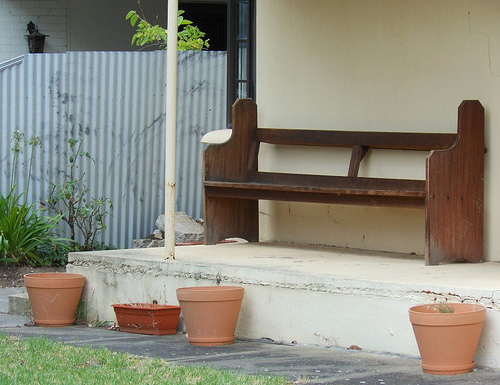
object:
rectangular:
[110, 297, 182, 334]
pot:
[108, 299, 179, 336]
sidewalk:
[97, 336, 358, 377]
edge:
[66, 253, 151, 281]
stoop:
[72, 256, 131, 329]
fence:
[33, 56, 156, 153]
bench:
[422, 149, 448, 264]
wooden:
[427, 151, 468, 268]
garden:
[50, 164, 105, 230]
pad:
[254, 235, 394, 327]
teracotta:
[95, 293, 189, 363]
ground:
[143, 338, 269, 379]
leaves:
[36, 138, 99, 233]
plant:
[49, 155, 109, 265]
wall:
[254, 318, 309, 383]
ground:
[18, 241, 159, 329]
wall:
[17, 52, 210, 213]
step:
[255, 258, 347, 315]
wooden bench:
[199, 98, 487, 263]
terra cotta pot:
[26, 271, 84, 329]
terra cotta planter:
[406, 300, 484, 374]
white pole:
[158, 3, 181, 258]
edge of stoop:
[6, 294, 33, 317]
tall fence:
[2, 40, 225, 253]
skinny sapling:
[5, 125, 42, 197]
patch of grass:
[1, 327, 285, 382]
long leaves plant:
[124, 5, 205, 49]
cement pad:
[65, 242, 500, 353]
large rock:
[147, 199, 200, 249]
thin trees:
[8, 125, 47, 208]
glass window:
[231, 3, 249, 115]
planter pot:
[21, 22, 49, 56]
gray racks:
[154, 207, 197, 242]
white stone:
[6, 281, 30, 318]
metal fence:
[0, 45, 223, 251]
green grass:
[2, 337, 289, 383]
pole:
[152, 3, 186, 261]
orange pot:
[404, 298, 484, 376]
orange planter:
[110, 299, 175, 335]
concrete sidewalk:
[65, 229, 490, 356]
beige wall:
[250, 2, 500, 257]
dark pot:
[110, 303, 181, 337]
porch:
[58, 234, 497, 358]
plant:
[0, 180, 62, 266]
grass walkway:
[62, 243, 499, 365]